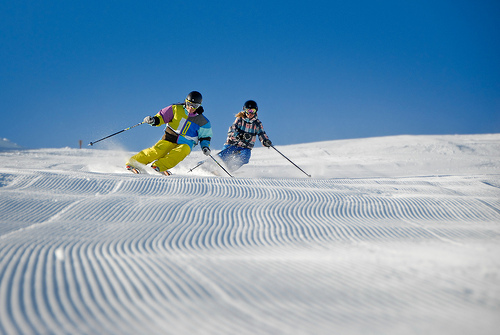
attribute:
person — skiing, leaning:
[221, 100, 275, 185]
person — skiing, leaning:
[133, 84, 213, 179]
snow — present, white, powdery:
[21, 169, 494, 328]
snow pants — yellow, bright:
[125, 133, 190, 175]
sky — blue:
[21, 13, 486, 89]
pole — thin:
[199, 152, 235, 178]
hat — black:
[246, 99, 258, 109]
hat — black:
[188, 90, 204, 103]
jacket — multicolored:
[149, 102, 212, 156]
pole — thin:
[270, 141, 319, 181]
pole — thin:
[73, 114, 149, 153]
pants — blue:
[217, 144, 254, 171]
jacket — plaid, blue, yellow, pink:
[222, 111, 275, 150]